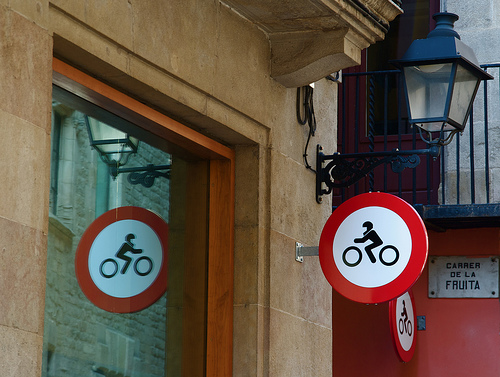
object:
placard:
[426, 254, 498, 299]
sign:
[319, 190, 428, 306]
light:
[391, 12, 491, 146]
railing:
[335, 62, 500, 209]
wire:
[295, 81, 317, 174]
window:
[43, 79, 214, 377]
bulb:
[424, 119, 444, 132]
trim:
[53, 57, 242, 166]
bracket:
[294, 241, 318, 260]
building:
[0, 1, 403, 377]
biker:
[342, 219, 400, 267]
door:
[333, 1, 440, 206]